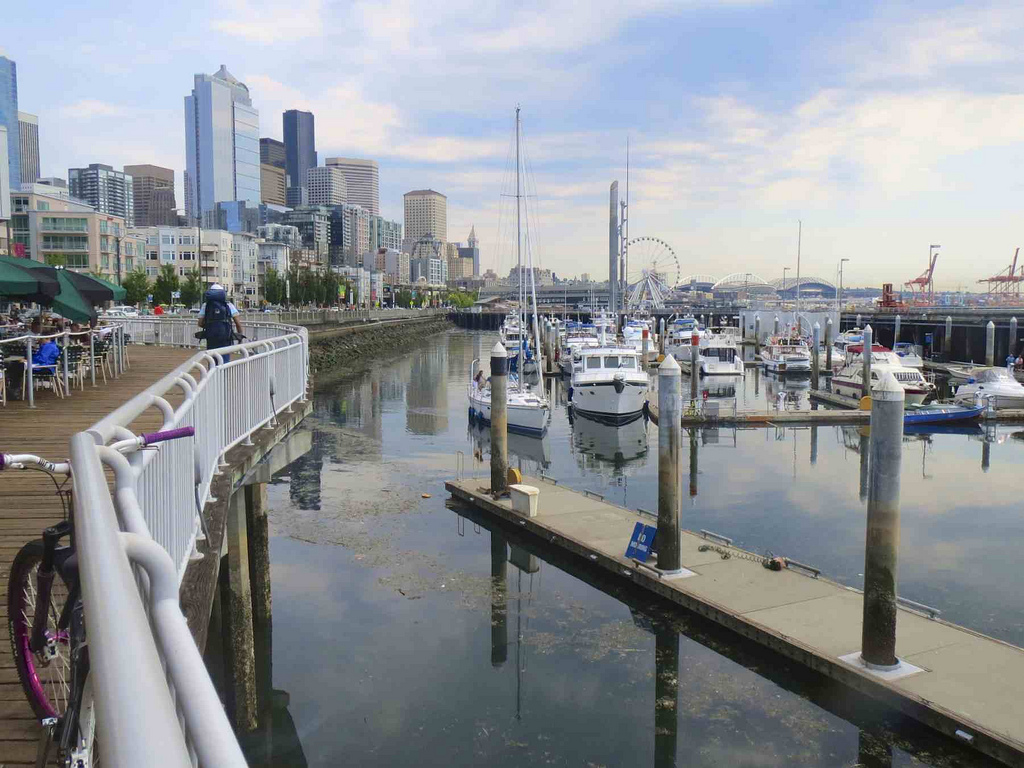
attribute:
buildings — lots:
[0, 55, 501, 290]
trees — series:
[252, 257, 364, 311]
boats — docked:
[423, 279, 1019, 422]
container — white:
[510, 483, 541, 518]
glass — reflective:
[205, 77, 255, 203]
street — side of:
[230, 268, 442, 331]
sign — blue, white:
[595, 499, 701, 575]